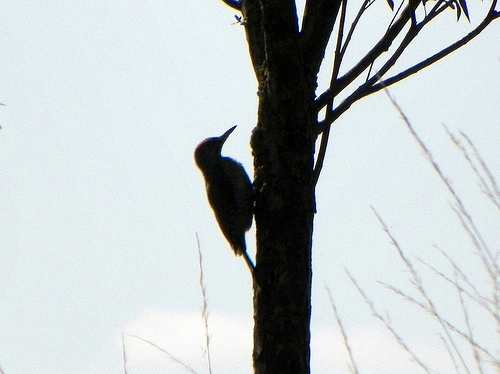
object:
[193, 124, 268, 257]
bird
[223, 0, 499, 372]
tree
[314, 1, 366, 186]
stem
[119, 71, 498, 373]
grass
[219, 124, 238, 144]
beak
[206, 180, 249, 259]
wings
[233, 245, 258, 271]
tail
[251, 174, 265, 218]
feet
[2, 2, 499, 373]
sky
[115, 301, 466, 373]
clouds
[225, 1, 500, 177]
branches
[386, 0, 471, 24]
leaves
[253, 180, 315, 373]
trunk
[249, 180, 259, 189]
leg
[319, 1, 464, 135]
branch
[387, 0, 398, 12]
leaf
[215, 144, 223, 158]
eye